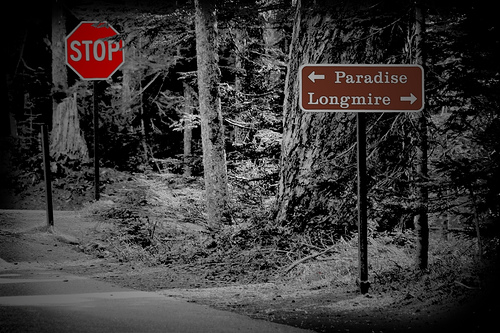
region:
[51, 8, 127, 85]
the stop sign is mostly red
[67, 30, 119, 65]
the letters are white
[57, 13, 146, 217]
the sign has a black pole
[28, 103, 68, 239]
a black pole in the ground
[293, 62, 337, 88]
an arrow pointing left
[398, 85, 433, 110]
an arrow pointing right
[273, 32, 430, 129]
the sign is brown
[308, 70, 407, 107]
the letters on the sign are white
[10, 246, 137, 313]
shadow of the trees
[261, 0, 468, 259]
a very big tree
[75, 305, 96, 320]
Black and white street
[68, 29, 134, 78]
Red and white stop sign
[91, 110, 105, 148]
Black pole that connects to stop sign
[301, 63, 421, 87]
Left arrow heading towards Paradise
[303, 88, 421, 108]
Right arrow heading towards Longmire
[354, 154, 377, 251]
Black pole that connects to the sign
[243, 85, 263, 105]
Small part of a branch off a tree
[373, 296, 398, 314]
Small patch of dirt in the ground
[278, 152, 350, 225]
Medium part of a huge oak of a tree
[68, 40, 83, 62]
White colored S on stop sign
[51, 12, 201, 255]
a stop sign on the side of the road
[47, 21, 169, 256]
a stop sign on a pole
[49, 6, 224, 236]
a stop sign on a metal pole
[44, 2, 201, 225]
a pole with a stop sign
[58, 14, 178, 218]
a metal pole with a stop sign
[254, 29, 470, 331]
a street sign on a pole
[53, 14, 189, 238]
a stop sign in the snow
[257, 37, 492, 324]
street sign on a pole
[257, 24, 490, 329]
street sign in the ground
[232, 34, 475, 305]
brown street sign on pole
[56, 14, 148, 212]
Sign on a post.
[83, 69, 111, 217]
The post is straight.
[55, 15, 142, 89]
The sign is red.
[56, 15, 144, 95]
The sign is octagonal.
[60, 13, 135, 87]
The sign has lettering.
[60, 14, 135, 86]
The lettering is white.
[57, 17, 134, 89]
The lettering is printed.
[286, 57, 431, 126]
The sign is rectangular.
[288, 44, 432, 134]
The sign is brown.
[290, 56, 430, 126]
Sign has directional arrows.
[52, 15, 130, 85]
octagon shaped stop sign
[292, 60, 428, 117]
sign with directions on the road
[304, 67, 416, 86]
directions to get to paradise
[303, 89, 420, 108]
directions to get to longmire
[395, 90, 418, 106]
arrow that is pointing right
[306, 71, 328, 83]
arrow that is pointing left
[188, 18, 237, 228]
trunk of pine tree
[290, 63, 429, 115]
brown and white sign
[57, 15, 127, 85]
red and white sign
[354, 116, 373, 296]
post holding up sign